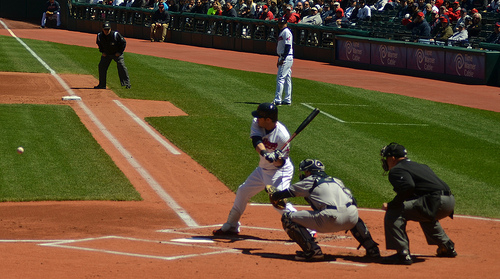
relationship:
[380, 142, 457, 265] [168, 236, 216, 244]
umpire behind home-plate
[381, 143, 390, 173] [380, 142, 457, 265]
facemask on umpire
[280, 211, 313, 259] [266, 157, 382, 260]
shinguard ont he catcher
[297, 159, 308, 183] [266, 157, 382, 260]
facemask on catcher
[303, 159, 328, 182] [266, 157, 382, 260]
helmet on catcher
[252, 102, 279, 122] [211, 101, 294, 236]
helmet on batter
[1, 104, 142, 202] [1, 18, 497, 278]
grass on field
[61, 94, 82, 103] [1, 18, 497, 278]
1st base on field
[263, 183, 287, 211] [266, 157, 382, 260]
glove of catcher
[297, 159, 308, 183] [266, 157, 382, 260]
facemask of catcher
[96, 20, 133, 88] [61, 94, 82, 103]
umpire beside 1st base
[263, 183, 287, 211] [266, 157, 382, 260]
glove on hand of catcher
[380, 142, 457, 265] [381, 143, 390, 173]
umpire wearing a facemask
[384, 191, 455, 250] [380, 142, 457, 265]
pants worn by umpire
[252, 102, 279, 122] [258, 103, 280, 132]
helmet on batters head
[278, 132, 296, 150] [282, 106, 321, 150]
handle of bat